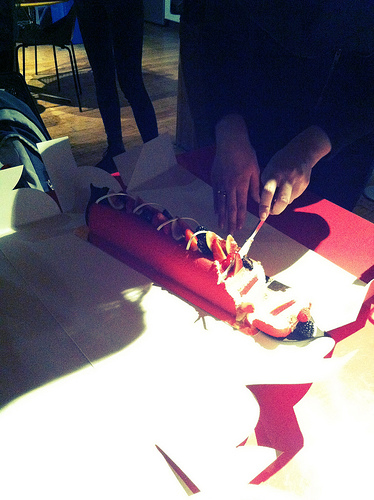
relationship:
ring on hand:
[216, 189, 228, 197] [209, 129, 262, 237]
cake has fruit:
[86, 183, 315, 340] [297, 322, 313, 340]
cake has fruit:
[86, 183, 315, 340] [299, 312, 308, 324]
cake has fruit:
[86, 183, 315, 340] [232, 252, 244, 275]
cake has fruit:
[86, 183, 315, 340] [242, 255, 253, 271]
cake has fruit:
[86, 183, 315, 340] [213, 236, 227, 260]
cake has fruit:
[86, 183, 315, 340] [225, 233, 239, 255]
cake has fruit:
[86, 183, 315, 340] [197, 238, 213, 256]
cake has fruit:
[86, 183, 315, 340] [196, 225, 207, 239]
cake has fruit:
[86, 183, 315, 340] [185, 228, 198, 252]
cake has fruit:
[86, 183, 315, 340] [106, 189, 125, 210]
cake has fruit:
[86, 183, 315, 340] [171, 220, 185, 243]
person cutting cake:
[179, 1, 373, 236] [86, 183, 315, 340]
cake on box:
[86, 183, 315, 340] [1, 131, 374, 498]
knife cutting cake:
[217, 219, 266, 286] [86, 183, 315, 340]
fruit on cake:
[171, 220, 185, 243] [86, 183, 315, 340]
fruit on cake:
[297, 322, 313, 340] [86, 183, 315, 340]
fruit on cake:
[242, 255, 253, 271] [86, 183, 315, 340]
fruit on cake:
[213, 236, 227, 260] [86, 183, 315, 340]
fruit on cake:
[106, 189, 125, 210] [86, 183, 315, 340]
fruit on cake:
[185, 228, 198, 252] [86, 183, 315, 340]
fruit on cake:
[157, 212, 172, 236] [86, 183, 315, 340]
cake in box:
[86, 183, 315, 340] [1, 131, 374, 498]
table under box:
[108, 144, 373, 285] [1, 131, 374, 498]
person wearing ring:
[179, 1, 373, 236] [216, 189, 228, 197]